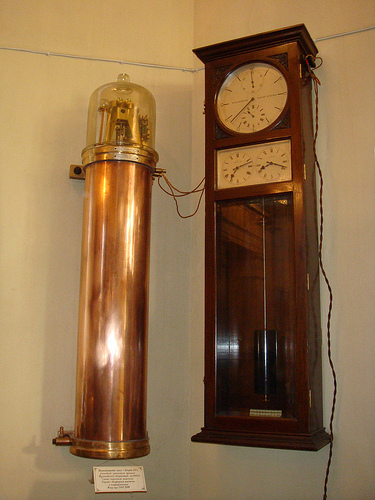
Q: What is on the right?
A: Clock.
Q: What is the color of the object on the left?
A: Copper.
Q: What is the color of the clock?
A: Gold.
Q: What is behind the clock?
A: Wire.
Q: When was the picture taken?
A: Daytime.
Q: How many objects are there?
A: Two.